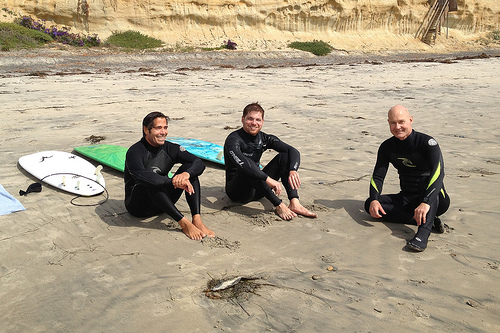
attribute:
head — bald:
[388, 102, 413, 137]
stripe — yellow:
[422, 159, 443, 194]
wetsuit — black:
[358, 131, 453, 235]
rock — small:
[317, 255, 347, 291]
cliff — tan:
[103, 8, 270, 66]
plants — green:
[110, 23, 151, 60]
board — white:
[13, 137, 115, 217]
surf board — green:
[69, 136, 132, 177]